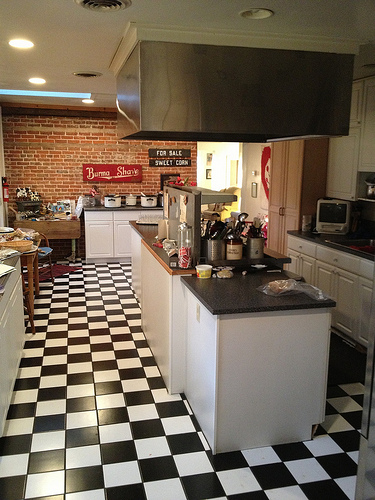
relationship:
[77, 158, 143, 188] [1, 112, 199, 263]
sign on wall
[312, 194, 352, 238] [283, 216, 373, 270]
tv on counter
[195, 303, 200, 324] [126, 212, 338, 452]
receptacle on island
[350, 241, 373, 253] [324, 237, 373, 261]
cloth on sink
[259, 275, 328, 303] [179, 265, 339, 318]
bag on counter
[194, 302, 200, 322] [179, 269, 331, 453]
receptacle built in to counter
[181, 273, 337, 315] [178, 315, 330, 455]
countertop on cabinet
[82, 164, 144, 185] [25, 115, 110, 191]
sign on wall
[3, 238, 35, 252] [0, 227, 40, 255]
basket on tabletop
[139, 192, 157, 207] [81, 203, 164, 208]
pot on counter top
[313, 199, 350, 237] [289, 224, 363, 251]
tv on countertop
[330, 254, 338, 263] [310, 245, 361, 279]
handle for drawer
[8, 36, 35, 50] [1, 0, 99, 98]
spotlight built in to ceiling